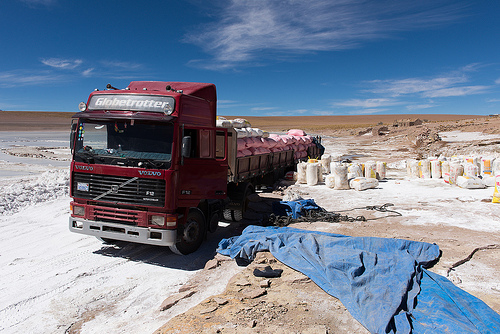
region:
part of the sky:
[349, 54, 378, 76]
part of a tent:
[348, 265, 381, 309]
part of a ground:
[238, 302, 267, 330]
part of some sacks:
[356, 177, 385, 192]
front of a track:
[101, 172, 156, 217]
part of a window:
[103, 114, 140, 152]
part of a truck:
[66, 172, 96, 194]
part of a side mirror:
[166, 137, 193, 174]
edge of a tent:
[318, 280, 345, 312]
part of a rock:
[236, 283, 272, 329]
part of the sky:
[320, 52, 359, 87]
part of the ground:
[241, 274, 273, 304]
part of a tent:
[332, 258, 378, 296]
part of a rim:
[171, 217, 203, 240]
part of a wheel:
[175, 207, 211, 262]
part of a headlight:
[141, 205, 169, 240]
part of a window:
[131, 138, 173, 166]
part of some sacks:
[413, 149, 460, 191]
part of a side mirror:
[175, 138, 189, 160]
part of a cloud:
[386, 50, 432, 109]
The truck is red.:
[88, 71, 243, 245]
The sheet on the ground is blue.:
[223, 213, 433, 332]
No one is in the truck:
[85, 115, 212, 157]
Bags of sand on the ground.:
[323, 158, 482, 198]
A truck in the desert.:
[36, 93, 476, 276]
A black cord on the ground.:
[448, 246, 493, 286]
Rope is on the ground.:
[272, 192, 433, 224]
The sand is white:
[18, 220, 116, 320]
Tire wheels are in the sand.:
[37, 250, 144, 313]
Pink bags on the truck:
[253, 133, 323, 153]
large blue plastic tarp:
[223, 222, 498, 332]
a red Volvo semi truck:
[70, 83, 327, 255]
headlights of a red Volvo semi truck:
[71, 203, 171, 227]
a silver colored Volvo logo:
[135, 168, 166, 181]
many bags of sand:
[298, 160, 498, 186]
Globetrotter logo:
[88, 95, 174, 112]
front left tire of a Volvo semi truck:
[170, 204, 212, 256]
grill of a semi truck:
[70, 168, 172, 207]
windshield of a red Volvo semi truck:
[70, 117, 185, 164]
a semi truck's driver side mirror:
[180, 134, 191, 159]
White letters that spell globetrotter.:
[61, 85, 183, 126]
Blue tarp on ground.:
[276, 214, 491, 332]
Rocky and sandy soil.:
[73, 258, 277, 328]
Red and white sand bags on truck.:
[215, 93, 320, 176]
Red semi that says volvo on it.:
[31, 62, 318, 267]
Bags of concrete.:
[308, 154, 433, 200]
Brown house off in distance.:
[356, 99, 438, 157]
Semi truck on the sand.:
[2, 62, 389, 294]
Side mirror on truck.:
[166, 125, 194, 165]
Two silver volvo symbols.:
[63, 153, 170, 178]